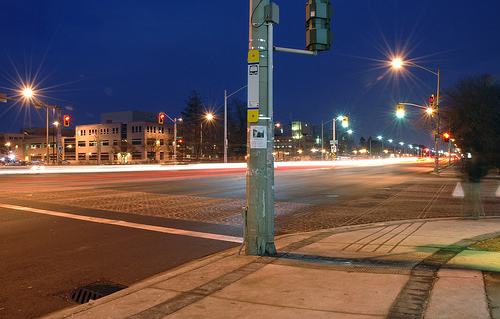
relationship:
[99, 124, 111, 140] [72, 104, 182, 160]
window on the building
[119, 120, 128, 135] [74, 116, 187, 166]
window on the building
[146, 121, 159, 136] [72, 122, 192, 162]
window on the building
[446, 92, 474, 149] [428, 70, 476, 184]
leaves on the tree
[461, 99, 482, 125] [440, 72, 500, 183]
leaves on the plant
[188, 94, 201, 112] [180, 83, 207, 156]
leaves on the tree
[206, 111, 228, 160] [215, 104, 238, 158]
leaves on the tree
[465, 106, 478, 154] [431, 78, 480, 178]
leaves on the tree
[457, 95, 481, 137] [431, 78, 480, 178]
leaves on the tree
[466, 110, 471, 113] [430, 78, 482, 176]
leaf on a plant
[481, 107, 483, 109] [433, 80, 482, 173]
leaf on a plant